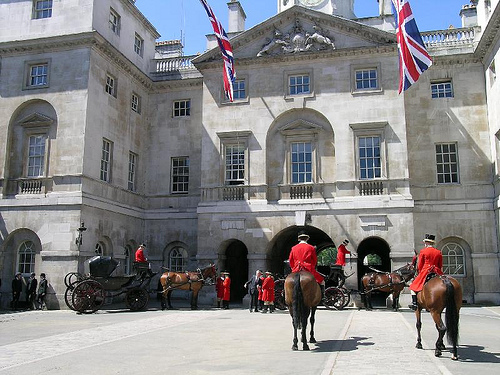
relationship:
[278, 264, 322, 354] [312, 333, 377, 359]
horse has shadow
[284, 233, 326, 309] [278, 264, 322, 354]
man riding horse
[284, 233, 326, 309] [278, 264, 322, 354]
man on horse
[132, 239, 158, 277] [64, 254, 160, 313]
man driving carriage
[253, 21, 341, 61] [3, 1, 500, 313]
figure on top of building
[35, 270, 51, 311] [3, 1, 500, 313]
person on side of building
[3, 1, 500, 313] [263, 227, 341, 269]
building has arch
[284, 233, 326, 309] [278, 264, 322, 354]
man riding on horse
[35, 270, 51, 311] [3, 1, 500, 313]
person standing by building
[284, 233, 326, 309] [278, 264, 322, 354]
man controlling horse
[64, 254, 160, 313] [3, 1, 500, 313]
carriage in front of building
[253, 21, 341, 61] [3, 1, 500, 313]
figure in front of building